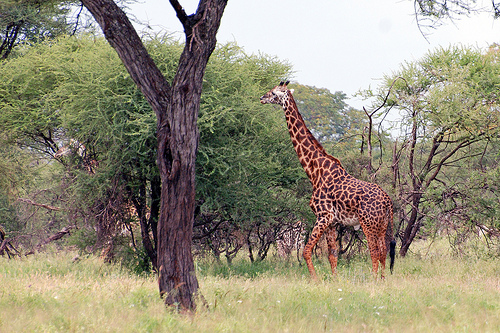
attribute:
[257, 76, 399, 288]
giraffe — walking, spotted, brown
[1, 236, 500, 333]
field — green, grass, dry, tall, white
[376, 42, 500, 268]
tree — brown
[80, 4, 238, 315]
tree — brown, split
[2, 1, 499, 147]
sky — blue, clear, grey, white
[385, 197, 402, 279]
tail — black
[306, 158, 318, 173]
spot — brown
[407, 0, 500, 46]
branch — barely visible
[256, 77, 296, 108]
head — white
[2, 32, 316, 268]
tree — green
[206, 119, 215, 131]
leaf — green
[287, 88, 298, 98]
ear — white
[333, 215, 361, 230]
under belly — white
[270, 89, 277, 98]
lashes — long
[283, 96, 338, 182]
neck — long